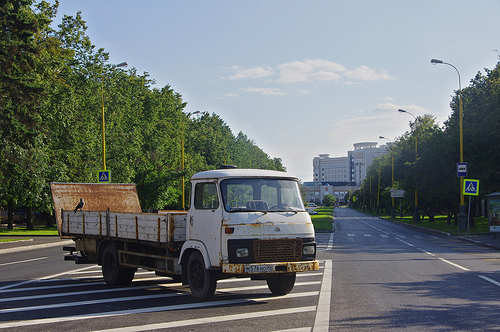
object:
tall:
[0, 0, 88, 229]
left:
[2, 0, 122, 331]